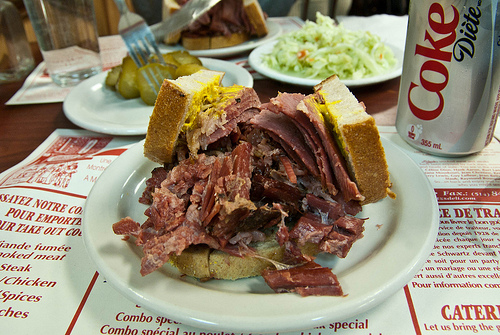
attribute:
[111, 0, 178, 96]
fork — silver, four pronged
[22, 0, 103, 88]
glass — clear, tall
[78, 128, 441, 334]
plate — white, round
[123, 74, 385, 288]
food — large, corned beef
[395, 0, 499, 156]
can — soda, silver, coke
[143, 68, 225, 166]
bread — small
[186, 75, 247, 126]
mustard — yellow, paste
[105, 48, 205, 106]
pickles — green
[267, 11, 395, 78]
lettuce — shredded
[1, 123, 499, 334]
mat — white, paper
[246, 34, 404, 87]
plate — white, smaller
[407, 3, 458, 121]
coke — red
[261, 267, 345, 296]
bacon — small, portion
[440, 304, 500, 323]
cater — red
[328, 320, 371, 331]
word — special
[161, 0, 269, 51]
sandwich — for other person